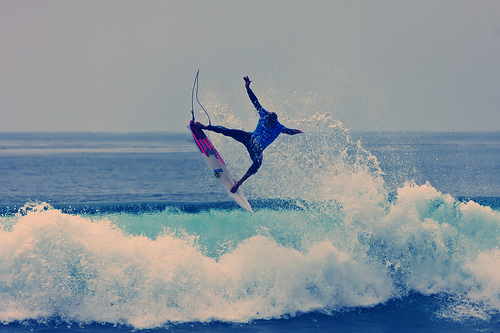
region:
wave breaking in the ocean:
[11, 196, 498, 323]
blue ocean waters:
[0, 133, 498, 331]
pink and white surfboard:
[190, 121, 254, 214]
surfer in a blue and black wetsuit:
[196, 72, 303, 195]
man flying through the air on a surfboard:
[188, 75, 301, 215]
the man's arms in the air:
[241, 75, 303, 135]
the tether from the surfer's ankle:
[187, 69, 211, 126]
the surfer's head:
[267, 111, 277, 129]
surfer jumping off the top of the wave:
[180, 63, 303, 219]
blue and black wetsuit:
[211, 90, 296, 178]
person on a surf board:
[138, 45, 320, 220]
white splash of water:
[18, 197, 481, 314]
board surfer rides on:
[182, 123, 252, 208]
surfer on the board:
[199, 73, 297, 168]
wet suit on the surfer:
[215, 90, 288, 175]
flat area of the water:
[15, 133, 487, 193]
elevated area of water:
[5, 184, 499, 221]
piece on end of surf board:
[183, 68, 210, 128]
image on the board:
[193, 133, 224, 156]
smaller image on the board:
[213, 164, 225, 181]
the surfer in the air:
[172, 51, 314, 221]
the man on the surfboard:
[180, 57, 315, 229]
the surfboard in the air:
[189, 115, 257, 221]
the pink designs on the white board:
[185, 121, 231, 164]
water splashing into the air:
[297, 89, 376, 194]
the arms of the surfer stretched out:
[242, 73, 313, 148]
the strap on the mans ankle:
[205, 118, 212, 133]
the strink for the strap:
[185, 59, 217, 135]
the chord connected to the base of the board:
[184, 86, 200, 128]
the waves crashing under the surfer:
[20, 193, 497, 310]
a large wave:
[8, 209, 448, 331]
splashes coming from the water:
[282, 127, 385, 212]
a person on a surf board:
[190, 73, 305, 210]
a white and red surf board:
[188, 105, 255, 215]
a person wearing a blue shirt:
[204, 82, 303, 192]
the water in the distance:
[28, 125, 185, 185]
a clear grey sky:
[10, 13, 177, 106]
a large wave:
[12, 201, 441, 269]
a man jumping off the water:
[185, 67, 355, 294]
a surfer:
[196, 78, 305, 198]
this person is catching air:
[164, 55, 386, 253]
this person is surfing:
[151, 20, 362, 297]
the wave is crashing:
[15, 188, 499, 315]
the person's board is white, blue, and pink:
[181, 106, 290, 256]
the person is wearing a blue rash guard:
[173, 45, 325, 250]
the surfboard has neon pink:
[177, 83, 273, 250]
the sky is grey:
[3, 3, 498, 166]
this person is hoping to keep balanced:
[111, 43, 389, 283]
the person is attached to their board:
[156, 43, 239, 150]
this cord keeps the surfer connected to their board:
[174, 44, 224, 142]